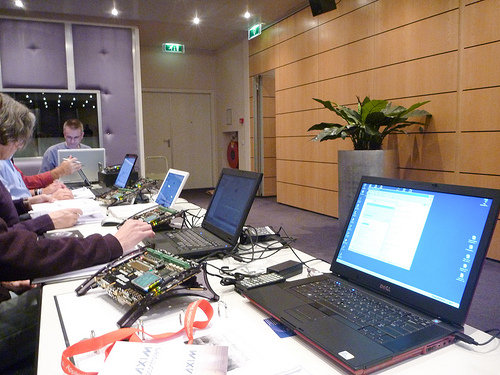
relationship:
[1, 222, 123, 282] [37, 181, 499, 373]
arm resting on table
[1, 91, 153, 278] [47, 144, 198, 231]
people working with laptops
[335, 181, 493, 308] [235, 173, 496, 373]
screen on laptop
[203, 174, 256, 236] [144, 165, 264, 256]
screen on laptop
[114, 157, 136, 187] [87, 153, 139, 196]
screen on laptop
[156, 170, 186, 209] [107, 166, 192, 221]
screen on laptop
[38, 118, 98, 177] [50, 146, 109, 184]
man working on laptop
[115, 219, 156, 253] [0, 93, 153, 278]
hand of people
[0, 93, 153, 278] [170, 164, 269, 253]
people working at laptop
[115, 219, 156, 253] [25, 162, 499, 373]
hand on table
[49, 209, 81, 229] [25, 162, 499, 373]
hand on table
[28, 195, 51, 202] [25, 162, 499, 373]
hand on table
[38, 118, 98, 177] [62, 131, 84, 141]
man wearing glasses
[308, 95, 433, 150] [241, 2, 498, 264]
green plant next to wall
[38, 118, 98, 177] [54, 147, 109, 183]
man looking at computer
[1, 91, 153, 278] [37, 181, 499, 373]
people sitting at table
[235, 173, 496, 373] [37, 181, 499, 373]
laptop on table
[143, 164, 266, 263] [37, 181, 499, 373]
laptop on table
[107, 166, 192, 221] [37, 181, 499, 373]
laptop on table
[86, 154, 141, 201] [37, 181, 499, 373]
laptop on table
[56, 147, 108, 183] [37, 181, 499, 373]
computer on table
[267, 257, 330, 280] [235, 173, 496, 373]
charger for laptop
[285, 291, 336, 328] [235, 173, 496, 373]
pad on laptop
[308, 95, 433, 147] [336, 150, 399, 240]
green plant in silver planter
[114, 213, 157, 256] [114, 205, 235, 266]
hand hovering over keyboard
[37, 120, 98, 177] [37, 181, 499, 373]
man sitting at end of table